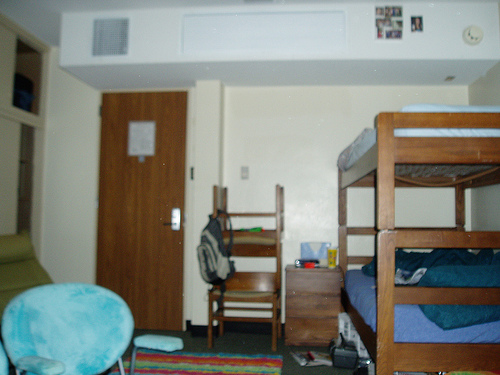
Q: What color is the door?
A: Brown.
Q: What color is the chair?
A: Brown.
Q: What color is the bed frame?
A: Brown.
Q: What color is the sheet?
A: Blue.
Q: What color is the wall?
A: White.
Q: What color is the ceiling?
A: White.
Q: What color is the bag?
A: White.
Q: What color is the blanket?
A: Blue green.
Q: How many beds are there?
A: Two.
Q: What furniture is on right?
A: Bunk bed.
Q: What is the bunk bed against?
A: Wall.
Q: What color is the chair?
A: Blue.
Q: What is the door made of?
A: Wood.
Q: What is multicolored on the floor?
A: Rug.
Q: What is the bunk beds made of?
A: Wood.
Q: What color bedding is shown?
A: Blue.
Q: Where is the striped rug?
A: On the floor.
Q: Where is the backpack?
A: Hanging on the chair.